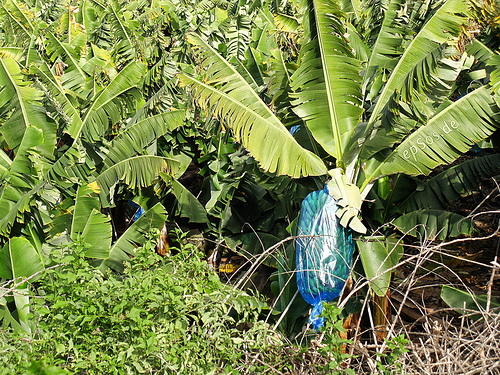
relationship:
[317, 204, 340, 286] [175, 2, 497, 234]
writing on tree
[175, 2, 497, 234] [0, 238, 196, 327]
tree has leaves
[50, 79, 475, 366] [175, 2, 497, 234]
field of tree